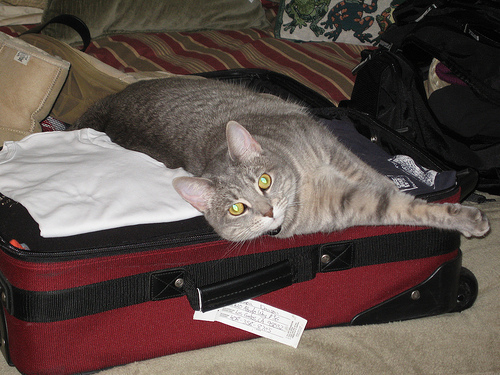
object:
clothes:
[0, 125, 216, 239]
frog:
[325, 4, 381, 47]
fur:
[302, 173, 353, 216]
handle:
[178, 251, 348, 312]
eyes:
[256, 175, 272, 191]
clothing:
[317, 116, 454, 191]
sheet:
[80, 24, 362, 105]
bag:
[0, 123, 477, 374]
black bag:
[352, 12, 499, 196]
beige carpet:
[353, 310, 452, 370]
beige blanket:
[220, 345, 389, 370]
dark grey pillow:
[49, 0, 263, 31]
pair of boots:
[2, 28, 136, 146]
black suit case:
[0, 171, 478, 372]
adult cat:
[62, 73, 490, 266]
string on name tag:
[192, 285, 211, 318]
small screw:
[320, 254, 333, 265]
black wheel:
[454, 269, 477, 312]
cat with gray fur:
[85, 83, 223, 158]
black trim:
[348, 228, 456, 259]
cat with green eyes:
[226, 200, 246, 218]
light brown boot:
[1, 28, 74, 139]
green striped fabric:
[165, 30, 255, 63]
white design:
[385, 175, 420, 191]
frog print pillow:
[279, 1, 384, 47]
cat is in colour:
[71, 70, 488, 244]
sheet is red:
[161, 23, 278, 55]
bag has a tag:
[196, 285, 308, 352]